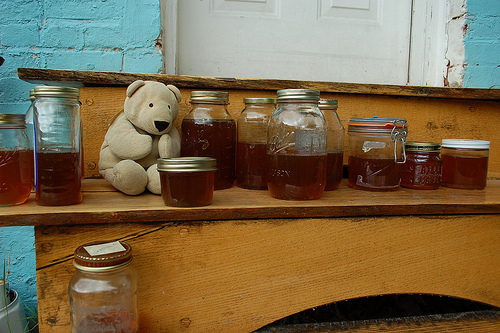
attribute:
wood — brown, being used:
[1, 67, 500, 332]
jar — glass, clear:
[0, 109, 35, 210]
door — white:
[174, 2, 417, 87]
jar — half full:
[31, 84, 84, 208]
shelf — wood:
[0, 178, 498, 228]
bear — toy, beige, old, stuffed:
[97, 79, 182, 195]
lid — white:
[440, 137, 493, 152]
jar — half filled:
[264, 86, 329, 201]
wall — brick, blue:
[1, 1, 498, 331]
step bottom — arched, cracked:
[33, 213, 498, 332]